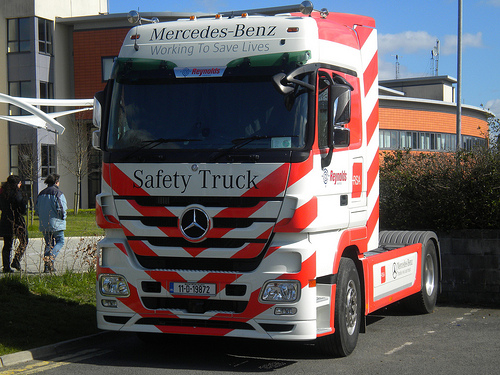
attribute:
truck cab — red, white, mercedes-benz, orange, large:
[85, 2, 449, 355]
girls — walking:
[5, 166, 73, 277]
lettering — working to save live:
[145, 38, 279, 58]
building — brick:
[2, 2, 101, 217]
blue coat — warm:
[34, 183, 72, 235]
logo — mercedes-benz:
[150, 23, 282, 41]